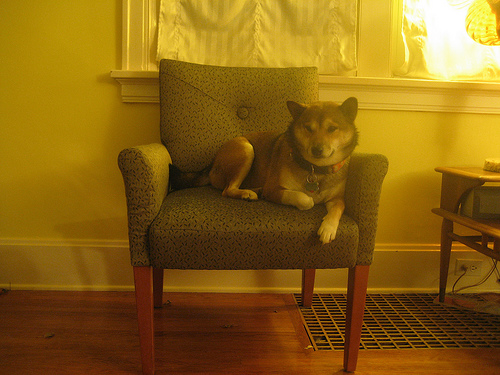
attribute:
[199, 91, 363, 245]
dog — shibu inu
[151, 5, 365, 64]
window coverings — pale, striped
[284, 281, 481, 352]
grate — large, floor, air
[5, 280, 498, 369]
flooring — hardwood, plank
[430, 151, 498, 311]
table — midcentury, side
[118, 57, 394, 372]
chair — midcentury, upholstered, neoclassical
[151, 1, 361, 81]
window — fabric-covered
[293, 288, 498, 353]
grating — metal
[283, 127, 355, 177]
collar — wide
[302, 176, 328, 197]
tags — hanging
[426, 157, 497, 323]
table — wooden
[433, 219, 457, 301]
leg — spindly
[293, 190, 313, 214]
paw — curled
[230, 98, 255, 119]
button — fabric-covered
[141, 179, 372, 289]
cushions — patterned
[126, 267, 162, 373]
legs — wooden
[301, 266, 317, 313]
legs — wooden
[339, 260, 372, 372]
legs — wooden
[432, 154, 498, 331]
table — end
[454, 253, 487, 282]
outlet — electric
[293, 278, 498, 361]
vent — heating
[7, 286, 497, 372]
floor — wooden, wood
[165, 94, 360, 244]
dog — contented, lounging, multicolored , big , sitting 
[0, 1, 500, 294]
wall — plain , plaster 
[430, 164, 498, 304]
end table — wood 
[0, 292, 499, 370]
floor — wood , hardwood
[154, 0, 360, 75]
curtain — light striped, striped white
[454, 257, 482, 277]
outlet — two plug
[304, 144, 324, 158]
nose — black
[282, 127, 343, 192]
collar — red, black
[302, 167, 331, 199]
dog tag — bone shaped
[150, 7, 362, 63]
curtain — white, striped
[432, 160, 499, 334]
end table — brown, wooden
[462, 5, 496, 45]
light shade — amber, glass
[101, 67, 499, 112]
window sill — white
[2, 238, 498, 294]
baseboard — white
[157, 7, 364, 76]
covering — white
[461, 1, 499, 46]
lamp shade — yellow, glass, swirly